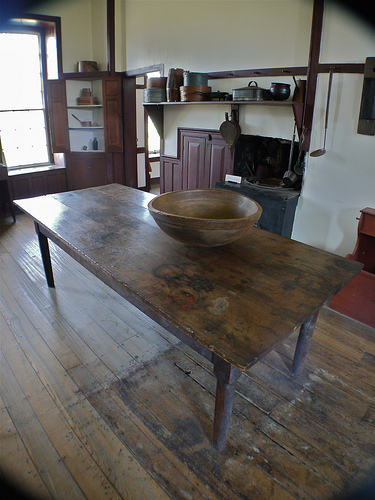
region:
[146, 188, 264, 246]
Giant bowl on a table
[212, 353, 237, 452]
Leg of a table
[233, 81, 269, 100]
Metal container on a shelf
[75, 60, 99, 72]
An old looking pot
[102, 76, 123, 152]
Cabinet door on a cabinet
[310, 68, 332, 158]
A wooden spoon on a rack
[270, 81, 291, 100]
A small black cauldron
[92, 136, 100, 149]
A bottle in a cabinet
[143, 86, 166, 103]
A container on a shelf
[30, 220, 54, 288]
A wooden leg on a table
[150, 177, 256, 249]
wooden bowl on table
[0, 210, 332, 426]
old wooden table with markings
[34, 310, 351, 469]
old wooden floor with damage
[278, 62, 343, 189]
kitchen utensils hanging on wall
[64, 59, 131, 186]
red painted corner cabinet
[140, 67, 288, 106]
assorted pots and pans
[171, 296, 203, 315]
red paint mark on table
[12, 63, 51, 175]
large window to left of room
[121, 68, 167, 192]
red trimmed open doorway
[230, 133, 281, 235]
old black cooking stove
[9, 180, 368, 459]
A large table is sitting in a kitchen.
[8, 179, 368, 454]
The color of a table is brown.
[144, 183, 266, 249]
A bowl is sitting on a table.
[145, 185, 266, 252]
The color of a bowl is brown.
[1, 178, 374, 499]
A kitchen has a wood floor.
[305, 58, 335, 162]
A ladle is hanging from a wall.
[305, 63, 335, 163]
The colors of a ladle are gray and brown.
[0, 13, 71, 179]
The sun is shining through a window.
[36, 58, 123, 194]
Doors to a piece of furniture are open.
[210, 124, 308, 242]
A stove is in the background.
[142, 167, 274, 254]
bowl on the table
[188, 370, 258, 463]
leg of the table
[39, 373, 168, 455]
lines on the ground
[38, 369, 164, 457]
hardwood on the ground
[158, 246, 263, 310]
brown and black table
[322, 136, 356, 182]
wall next to the table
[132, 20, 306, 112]
pots above the ground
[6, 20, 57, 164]
window in the room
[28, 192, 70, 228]
light on the table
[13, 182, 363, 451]
heavy old wooden table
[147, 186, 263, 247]
big wooden mixing bowl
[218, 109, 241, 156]
antique cloth fire blower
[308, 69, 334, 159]
hanging long metal ladel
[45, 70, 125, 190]
antique wooden storage cabinet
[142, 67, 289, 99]
old pots and pans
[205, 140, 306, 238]
old black fire stove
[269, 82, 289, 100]
round black ceramic vase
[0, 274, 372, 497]
old wooden floor boards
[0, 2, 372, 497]
display of a historical kitchen